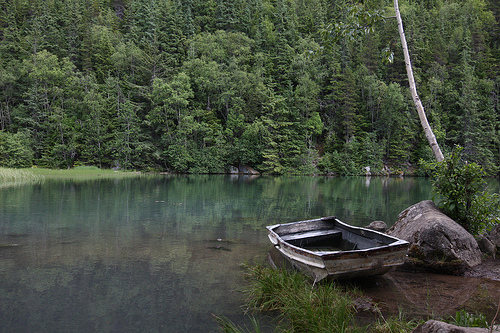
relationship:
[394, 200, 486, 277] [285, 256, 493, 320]
rock on shore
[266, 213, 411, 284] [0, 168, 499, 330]
boat in water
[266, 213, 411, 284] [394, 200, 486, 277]
boat near rock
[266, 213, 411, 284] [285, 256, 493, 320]
boat on shore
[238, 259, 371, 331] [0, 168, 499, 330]
grass in water